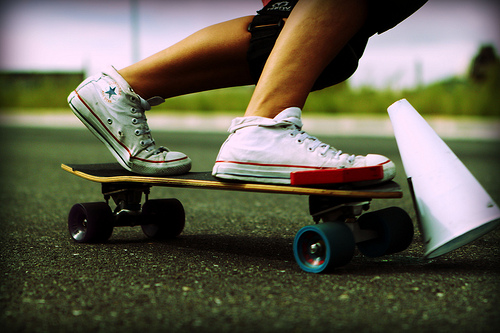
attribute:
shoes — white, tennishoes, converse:
[67, 64, 398, 188]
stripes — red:
[73, 88, 392, 170]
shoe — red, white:
[67, 63, 193, 175]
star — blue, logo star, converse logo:
[105, 85, 120, 99]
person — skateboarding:
[67, 0, 398, 187]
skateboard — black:
[60, 159, 415, 272]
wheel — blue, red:
[293, 221, 355, 274]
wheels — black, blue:
[68, 198, 415, 258]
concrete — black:
[2, 126, 500, 329]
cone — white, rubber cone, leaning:
[387, 98, 500, 263]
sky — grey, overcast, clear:
[4, 2, 500, 89]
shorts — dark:
[247, 3, 427, 92]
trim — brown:
[58, 162, 405, 199]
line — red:
[74, 88, 189, 163]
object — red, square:
[289, 164, 386, 185]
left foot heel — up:
[66, 66, 126, 133]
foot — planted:
[211, 107, 399, 185]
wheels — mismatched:
[68, 197, 415, 274]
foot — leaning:
[67, 64, 193, 175]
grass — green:
[4, 71, 496, 115]